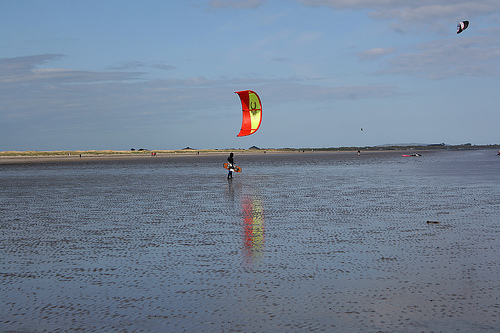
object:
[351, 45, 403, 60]
cloud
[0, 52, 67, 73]
clouds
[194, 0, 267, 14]
clouds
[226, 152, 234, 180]
man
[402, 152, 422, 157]
kite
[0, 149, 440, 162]
ground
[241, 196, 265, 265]
reflection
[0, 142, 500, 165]
field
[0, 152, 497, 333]
water surface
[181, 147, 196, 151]
dune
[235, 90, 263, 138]
kite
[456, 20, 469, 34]
kite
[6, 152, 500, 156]
shore line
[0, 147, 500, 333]
shore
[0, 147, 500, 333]
beach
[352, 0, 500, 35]
cloud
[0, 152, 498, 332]
ocean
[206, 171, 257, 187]
sand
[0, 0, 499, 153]
air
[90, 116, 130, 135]
clouds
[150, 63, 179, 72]
clouds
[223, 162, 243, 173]
surfboard